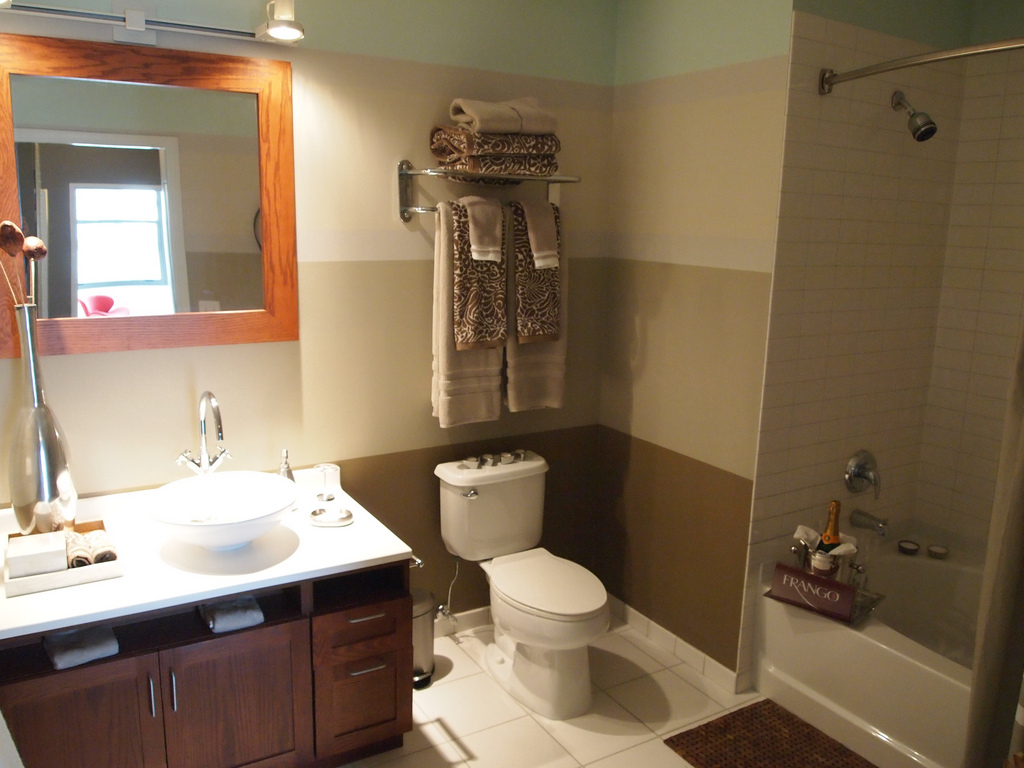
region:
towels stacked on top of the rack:
[431, 72, 572, 191]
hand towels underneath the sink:
[40, 587, 291, 663]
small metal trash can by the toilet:
[403, 590, 457, 690]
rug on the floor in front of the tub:
[660, 702, 870, 764]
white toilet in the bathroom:
[438, 449, 642, 696]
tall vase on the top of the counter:
[3, 233, 79, 554]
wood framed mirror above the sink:
[0, 22, 295, 355]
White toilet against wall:
[434, 442, 616, 719]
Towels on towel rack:
[431, 194, 571, 428]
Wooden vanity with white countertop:
[2, 464, 418, 762]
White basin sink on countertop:
[146, 469, 306, 562]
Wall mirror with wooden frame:
[2, 25, 303, 352]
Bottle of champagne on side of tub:
[800, 498, 857, 601]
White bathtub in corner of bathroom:
[763, 513, 1020, 767]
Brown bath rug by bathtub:
[662, 697, 877, 767]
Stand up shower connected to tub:
[756, 3, 1020, 766]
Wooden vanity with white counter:
[2, 457, 417, 767]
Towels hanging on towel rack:
[425, 195, 574, 429]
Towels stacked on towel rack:
[425, 91, 566, 181]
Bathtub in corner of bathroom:
[748, 515, 1023, 766]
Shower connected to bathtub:
[750, 8, 1020, 767]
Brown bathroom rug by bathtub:
[665, 695, 884, 766]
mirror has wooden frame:
[0, 29, 302, 358]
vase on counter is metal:
[13, 303, 72, 532]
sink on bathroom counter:
[149, 389, 301, 549]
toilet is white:
[433, 454, 614, 723]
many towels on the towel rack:
[396, 94, 586, 433]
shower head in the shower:
[887, 89, 936, 144]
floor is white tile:
[307, 604, 764, 764]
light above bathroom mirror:
[260, 2, 305, 44]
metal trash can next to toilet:
[409, 588, 441, 687]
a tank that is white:
[416, 450, 552, 550]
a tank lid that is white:
[434, 454, 532, 484]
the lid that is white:
[500, 549, 612, 625]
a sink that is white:
[144, 441, 301, 571]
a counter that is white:
[4, 505, 413, 636]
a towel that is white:
[27, 489, 113, 572]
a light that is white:
[232, 12, 332, 55]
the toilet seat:
[482, 560, 628, 646]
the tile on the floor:
[495, 707, 543, 755]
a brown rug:
[707, 731, 796, 766]